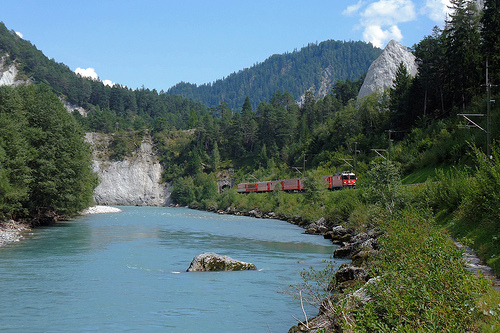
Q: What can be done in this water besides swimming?
A: Boating.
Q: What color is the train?
A: Red.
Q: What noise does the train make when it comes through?
A: A whistle.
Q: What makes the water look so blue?
A: The sky's reflection.